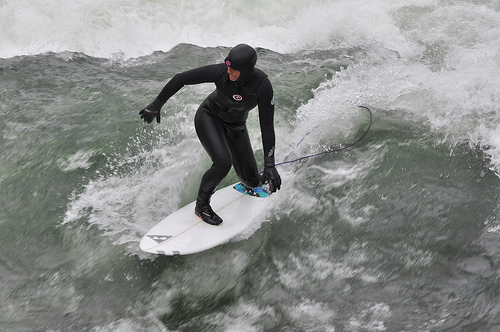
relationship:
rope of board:
[259, 102, 372, 170] [136, 172, 294, 257]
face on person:
[224, 57, 242, 82] [141, 45, 301, 228]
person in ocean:
[137, 42, 284, 229] [376, 41, 476, 278]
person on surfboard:
[137, 42, 284, 229] [137, 173, 280, 257]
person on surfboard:
[134, 32, 286, 233] [136, 172, 293, 261]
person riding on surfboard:
[134, 32, 286, 233] [136, 172, 293, 261]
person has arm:
[137, 42, 284, 229] [119, 46, 210, 148]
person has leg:
[134, 32, 286, 233] [181, 110, 230, 236]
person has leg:
[134, 32, 286, 233] [223, 123, 268, 190]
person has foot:
[137, 42, 284, 229] [191, 200, 230, 232]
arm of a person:
[149, 64, 221, 110] [134, 32, 286, 233]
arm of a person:
[131, 60, 218, 130] [134, 32, 286, 233]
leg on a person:
[194, 110, 234, 223] [137, 43, 282, 225]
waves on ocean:
[66, 179, 253, 301] [4, 4, 498, 330]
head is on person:
[222, 42, 261, 79] [160, 40, 281, 214]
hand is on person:
[136, 104, 164, 125] [134, 32, 286, 233]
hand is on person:
[260, 162, 283, 192] [134, 32, 286, 233]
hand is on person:
[138, 105, 163, 123] [137, 43, 282, 225]